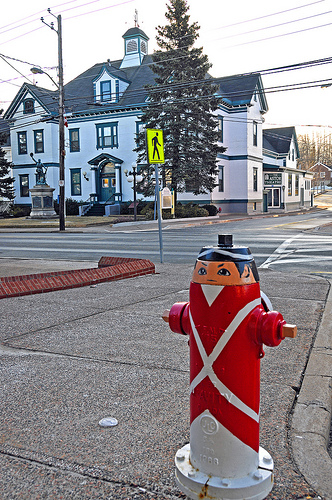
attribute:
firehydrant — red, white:
[160, 245, 295, 476]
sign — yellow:
[140, 123, 167, 174]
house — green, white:
[7, 19, 266, 212]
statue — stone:
[24, 144, 57, 219]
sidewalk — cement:
[3, 223, 144, 237]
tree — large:
[142, 0, 224, 208]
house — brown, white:
[307, 157, 332, 193]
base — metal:
[33, 189, 59, 219]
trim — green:
[94, 117, 118, 129]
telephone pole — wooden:
[54, 17, 72, 233]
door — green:
[88, 162, 130, 201]